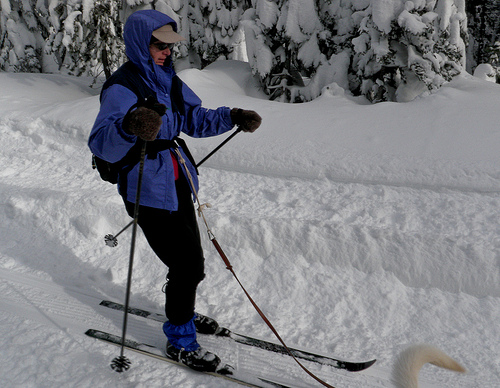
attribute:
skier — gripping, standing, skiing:
[86, 9, 260, 368]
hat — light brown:
[153, 25, 182, 44]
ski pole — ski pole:
[102, 128, 240, 245]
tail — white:
[393, 343, 464, 386]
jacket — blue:
[87, 12, 234, 211]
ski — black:
[98, 298, 376, 371]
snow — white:
[2, 69, 499, 387]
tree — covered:
[243, 0, 469, 103]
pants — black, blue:
[126, 177, 200, 347]